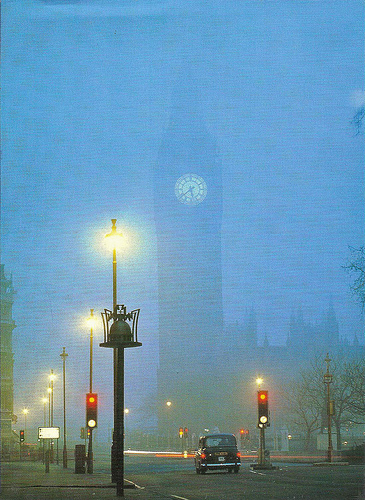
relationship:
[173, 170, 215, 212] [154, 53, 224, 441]
clock on side of building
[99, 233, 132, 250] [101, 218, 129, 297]
light on pole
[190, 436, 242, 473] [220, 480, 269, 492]
car driving on road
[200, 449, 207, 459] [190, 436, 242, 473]
light on back of car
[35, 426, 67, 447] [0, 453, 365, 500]
sign on road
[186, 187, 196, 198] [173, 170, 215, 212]
hands inside a clock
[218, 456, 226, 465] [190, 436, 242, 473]
license plate of a car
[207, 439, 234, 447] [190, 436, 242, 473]
window of a car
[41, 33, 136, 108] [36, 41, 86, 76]
fog in sky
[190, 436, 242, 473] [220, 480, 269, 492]
car driving on a road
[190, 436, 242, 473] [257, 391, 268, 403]
car stopped at light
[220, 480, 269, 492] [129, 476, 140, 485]
road has edge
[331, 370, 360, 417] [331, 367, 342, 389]
tree has branch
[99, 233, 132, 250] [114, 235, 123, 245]
light has part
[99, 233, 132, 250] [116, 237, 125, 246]
light has part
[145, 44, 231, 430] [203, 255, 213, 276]
building has part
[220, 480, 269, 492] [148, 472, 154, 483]
road has side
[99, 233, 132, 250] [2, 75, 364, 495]
light in city